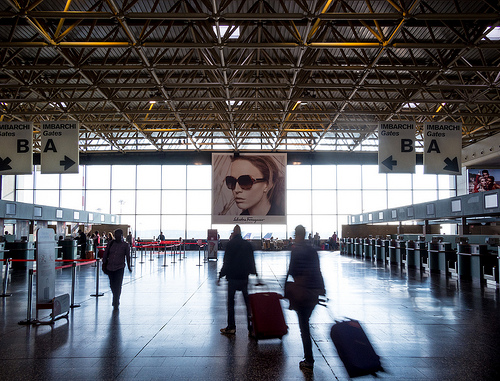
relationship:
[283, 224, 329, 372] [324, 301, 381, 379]
person carrying bag